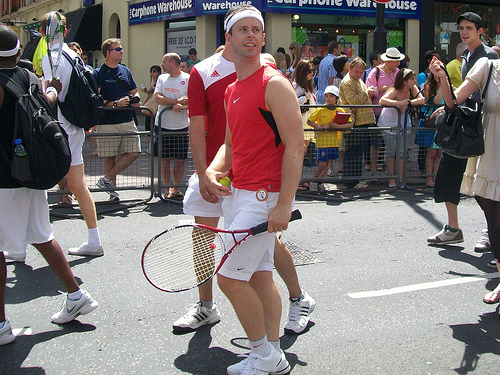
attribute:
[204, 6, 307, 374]
player — walking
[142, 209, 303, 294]
tennis racket — black, red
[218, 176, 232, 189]
tennis ball — green, yellow-green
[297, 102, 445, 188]
barrier — gray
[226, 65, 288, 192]
shirt — red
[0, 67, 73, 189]
backpack — black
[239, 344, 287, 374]
shoe — tennis shoe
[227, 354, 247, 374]
shoe — tennis shoe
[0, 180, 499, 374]
street — gray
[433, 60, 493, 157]
purse — black, large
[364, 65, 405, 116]
shirt — pink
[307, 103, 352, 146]
shirt — yellow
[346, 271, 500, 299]
stripe — white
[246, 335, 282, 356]
socks — nike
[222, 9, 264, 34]
sweatband — white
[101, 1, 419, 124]
building — white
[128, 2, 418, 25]
sign — blue, white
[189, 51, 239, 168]
shirt — adidas, red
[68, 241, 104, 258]
shoe — white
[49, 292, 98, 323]
shoe — white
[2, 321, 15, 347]
shoe — white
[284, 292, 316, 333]
shoe — white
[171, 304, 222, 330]
shoe — white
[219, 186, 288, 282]
shorts — white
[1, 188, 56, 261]
shorts — white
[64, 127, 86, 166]
shorts — white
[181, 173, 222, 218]
shorts — white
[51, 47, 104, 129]
backpack — black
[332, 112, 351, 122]
book — red